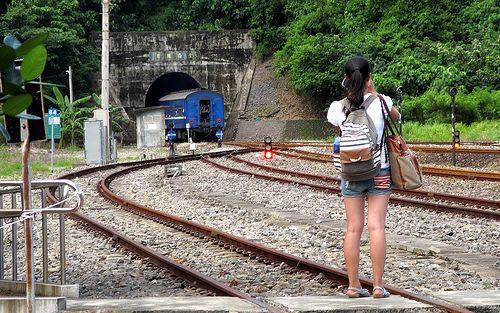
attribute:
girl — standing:
[327, 57, 400, 295]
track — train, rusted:
[46, 140, 474, 312]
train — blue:
[157, 88, 226, 138]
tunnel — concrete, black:
[146, 73, 201, 108]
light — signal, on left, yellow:
[265, 137, 273, 158]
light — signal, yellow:
[454, 130, 460, 149]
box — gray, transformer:
[85, 119, 116, 165]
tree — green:
[43, 87, 92, 146]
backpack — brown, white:
[334, 92, 380, 183]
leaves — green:
[0, 31, 49, 116]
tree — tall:
[0, 1, 101, 144]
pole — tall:
[101, 2, 108, 107]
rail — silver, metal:
[1, 179, 83, 282]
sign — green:
[45, 114, 61, 138]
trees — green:
[108, 0, 498, 119]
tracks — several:
[46, 138, 500, 311]